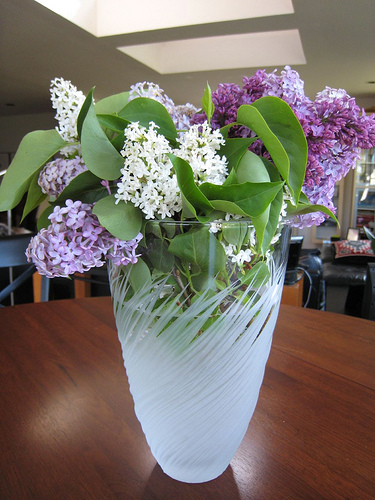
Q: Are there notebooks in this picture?
A: No, there are no notebooks.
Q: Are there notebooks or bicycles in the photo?
A: No, there are no notebooks or bicycles.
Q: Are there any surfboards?
A: No, there are no surfboards.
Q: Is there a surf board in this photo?
A: No, there are no surfboards.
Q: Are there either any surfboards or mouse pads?
A: No, there are no surfboards or mouse pads.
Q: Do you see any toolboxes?
A: No, there are no toolboxes.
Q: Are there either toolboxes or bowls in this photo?
A: No, there are no toolboxes or bowls.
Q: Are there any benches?
A: No, there are no benches.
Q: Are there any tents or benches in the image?
A: No, there are no benches or tents.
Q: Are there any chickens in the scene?
A: No, there are no chickens.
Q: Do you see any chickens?
A: No, there are no chickens.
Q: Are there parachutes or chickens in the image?
A: No, there are no chickens or parachutes.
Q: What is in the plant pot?
A: The flowers are in the plant pot.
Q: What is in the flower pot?
A: The flowers are in the plant pot.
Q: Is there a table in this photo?
A: Yes, there is a table.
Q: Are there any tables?
A: Yes, there is a table.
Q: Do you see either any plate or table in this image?
A: Yes, there is a table.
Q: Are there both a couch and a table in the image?
A: Yes, there are both a table and a couch.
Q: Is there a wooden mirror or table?
A: Yes, there is a wood table.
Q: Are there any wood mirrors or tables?
A: Yes, there is a wood table.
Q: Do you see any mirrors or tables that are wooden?
A: Yes, the table is wooden.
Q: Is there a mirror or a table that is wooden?
A: Yes, the table is wooden.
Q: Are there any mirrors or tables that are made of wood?
A: Yes, the table is made of wood.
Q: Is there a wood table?
A: Yes, there is a wood table.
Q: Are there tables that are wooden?
A: Yes, there is a table that is wooden.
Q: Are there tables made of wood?
A: Yes, there is a table that is made of wood.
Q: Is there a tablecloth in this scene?
A: No, there are no tablecloths.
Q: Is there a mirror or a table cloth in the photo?
A: No, there are no tablecloths or mirrors.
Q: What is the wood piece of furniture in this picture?
A: The piece of furniture is a table.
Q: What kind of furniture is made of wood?
A: The furniture is a table.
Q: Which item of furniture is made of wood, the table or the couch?
A: The table is made of wood.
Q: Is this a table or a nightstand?
A: This is a table.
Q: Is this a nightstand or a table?
A: This is a table.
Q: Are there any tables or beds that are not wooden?
A: No, there is a table but it is wooden.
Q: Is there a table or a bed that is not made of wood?
A: No, there is a table but it is made of wood.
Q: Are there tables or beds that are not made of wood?
A: No, there is a table but it is made of wood.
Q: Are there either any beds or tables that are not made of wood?
A: No, there is a table but it is made of wood.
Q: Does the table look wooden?
A: Yes, the table is wooden.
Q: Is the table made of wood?
A: Yes, the table is made of wood.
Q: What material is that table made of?
A: The table is made of wood.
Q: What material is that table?
A: The table is made of wood.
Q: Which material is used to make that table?
A: The table is made of wood.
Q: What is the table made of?
A: The table is made of wood.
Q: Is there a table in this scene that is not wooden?
A: No, there is a table but it is wooden.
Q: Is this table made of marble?
A: No, the table is made of wood.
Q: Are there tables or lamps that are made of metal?
A: No, there is a table but it is made of wood.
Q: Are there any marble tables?
A: No, there is a table but it is made of wood.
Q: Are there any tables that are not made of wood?
A: No, there is a table but it is made of wood.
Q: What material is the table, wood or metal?
A: The table is made of wood.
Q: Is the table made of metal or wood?
A: The table is made of wood.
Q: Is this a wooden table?
A: Yes, this is a wooden table.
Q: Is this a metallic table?
A: No, this is a wooden table.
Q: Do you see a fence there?
A: No, there are no fences.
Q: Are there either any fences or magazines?
A: No, there are no fences or magazines.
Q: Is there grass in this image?
A: Yes, there is grass.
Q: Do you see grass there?
A: Yes, there is grass.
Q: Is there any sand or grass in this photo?
A: Yes, there is grass.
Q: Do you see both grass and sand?
A: No, there is grass but no sand.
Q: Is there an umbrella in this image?
A: No, there are no umbrellas.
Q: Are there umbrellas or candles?
A: No, there are no umbrellas or candles.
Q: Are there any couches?
A: Yes, there is a couch.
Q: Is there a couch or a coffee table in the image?
A: Yes, there is a couch.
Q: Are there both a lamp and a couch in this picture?
A: No, there is a couch but no lamps.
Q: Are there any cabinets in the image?
A: No, there are no cabinets.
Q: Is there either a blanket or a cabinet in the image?
A: No, there are no cabinets or blankets.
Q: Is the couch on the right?
A: Yes, the couch is on the right of the image.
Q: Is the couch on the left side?
A: No, the couch is on the right of the image.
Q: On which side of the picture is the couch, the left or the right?
A: The couch is on the right of the image.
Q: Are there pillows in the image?
A: Yes, there is a pillow.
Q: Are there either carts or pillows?
A: Yes, there is a pillow.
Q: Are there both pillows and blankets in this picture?
A: No, there is a pillow but no blankets.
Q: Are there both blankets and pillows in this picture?
A: No, there is a pillow but no blankets.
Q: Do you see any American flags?
A: No, there are no American flags.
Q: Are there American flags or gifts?
A: No, there are no American flags or gifts.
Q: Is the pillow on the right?
A: Yes, the pillow is on the right of the image.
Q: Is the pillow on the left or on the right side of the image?
A: The pillow is on the right of the image.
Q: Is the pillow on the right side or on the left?
A: The pillow is on the right of the image.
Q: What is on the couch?
A: The pillow is on the couch.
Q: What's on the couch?
A: The pillow is on the couch.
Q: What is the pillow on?
A: The pillow is on the couch.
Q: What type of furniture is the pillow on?
A: The pillow is on the couch.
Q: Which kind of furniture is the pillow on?
A: The pillow is on the couch.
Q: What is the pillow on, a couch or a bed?
A: The pillow is on a couch.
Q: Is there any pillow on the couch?
A: Yes, there is a pillow on the couch.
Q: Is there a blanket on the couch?
A: No, there is a pillow on the couch.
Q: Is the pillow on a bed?
A: No, the pillow is on the couch.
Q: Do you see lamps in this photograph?
A: No, there are no lamps.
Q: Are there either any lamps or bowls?
A: No, there are no lamps or bowls.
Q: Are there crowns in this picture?
A: No, there are no crowns.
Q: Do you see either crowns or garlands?
A: No, there are no crowns or garlands.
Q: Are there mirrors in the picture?
A: No, there are no mirrors.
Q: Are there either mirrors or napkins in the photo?
A: No, there are no mirrors or napkins.